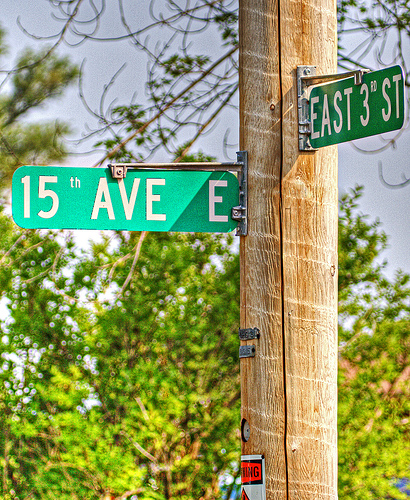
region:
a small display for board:
[276, 50, 407, 140]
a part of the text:
[198, 442, 299, 497]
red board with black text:
[235, 455, 267, 489]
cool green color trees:
[38, 314, 408, 494]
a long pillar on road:
[227, 27, 363, 483]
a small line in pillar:
[269, 250, 300, 498]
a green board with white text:
[19, 154, 266, 249]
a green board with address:
[13, 148, 261, 245]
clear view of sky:
[69, 13, 404, 176]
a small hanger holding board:
[294, 67, 380, 85]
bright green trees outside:
[43, 270, 191, 469]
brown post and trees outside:
[285, 254, 400, 473]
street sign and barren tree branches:
[36, 46, 257, 238]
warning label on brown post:
[234, 461, 276, 497]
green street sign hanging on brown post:
[252, 4, 401, 175]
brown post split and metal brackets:
[232, 254, 314, 414]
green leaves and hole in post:
[208, 398, 266, 443]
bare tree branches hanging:
[8, 9, 194, 121]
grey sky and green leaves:
[360, 187, 404, 254]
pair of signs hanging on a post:
[44, 76, 397, 221]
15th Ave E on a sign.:
[13, 169, 237, 226]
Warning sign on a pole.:
[228, 443, 273, 498]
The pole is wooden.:
[239, 60, 340, 498]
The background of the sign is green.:
[11, 167, 242, 241]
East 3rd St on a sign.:
[299, 73, 409, 132]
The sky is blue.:
[27, 14, 189, 131]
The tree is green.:
[36, 395, 175, 498]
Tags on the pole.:
[225, 320, 267, 369]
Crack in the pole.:
[269, 271, 295, 498]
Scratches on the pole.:
[294, 236, 342, 330]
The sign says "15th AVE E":
[15, 158, 242, 245]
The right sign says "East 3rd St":
[290, 70, 407, 138]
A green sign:
[19, 166, 248, 242]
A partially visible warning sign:
[233, 447, 271, 498]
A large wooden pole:
[222, 13, 354, 493]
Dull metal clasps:
[235, 327, 267, 367]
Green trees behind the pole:
[8, 251, 235, 495]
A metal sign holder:
[107, 155, 263, 231]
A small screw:
[109, 166, 125, 180]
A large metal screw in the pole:
[228, 414, 258, 443]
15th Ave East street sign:
[4, 149, 253, 271]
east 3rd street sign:
[281, 56, 402, 153]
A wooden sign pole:
[221, 104, 351, 407]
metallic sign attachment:
[206, 138, 263, 257]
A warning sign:
[233, 445, 272, 498]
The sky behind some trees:
[12, 5, 239, 115]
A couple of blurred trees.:
[93, 353, 216, 494]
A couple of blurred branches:
[160, 69, 227, 131]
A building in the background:
[341, 329, 408, 419]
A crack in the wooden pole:
[266, 264, 298, 490]